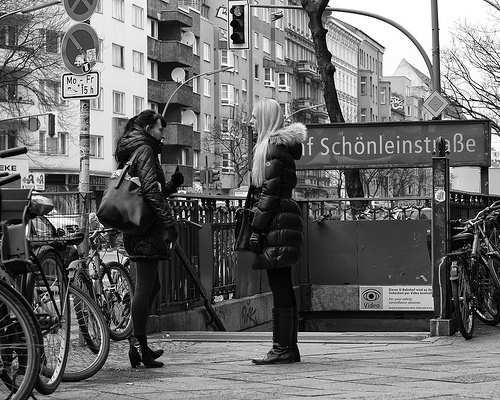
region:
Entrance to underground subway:
[212, 190, 449, 350]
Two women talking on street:
[102, 94, 327, 369]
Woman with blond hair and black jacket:
[230, 84, 314, 271]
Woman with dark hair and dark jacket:
[95, 102, 182, 260]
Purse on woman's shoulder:
[93, 161, 156, 240]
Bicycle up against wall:
[443, 193, 498, 341]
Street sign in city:
[52, 1, 106, 231]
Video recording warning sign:
[352, 283, 447, 316]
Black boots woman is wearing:
[246, 301, 310, 373]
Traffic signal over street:
[215, 0, 272, 56]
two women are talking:
[108, 91, 390, 395]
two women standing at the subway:
[85, 70, 383, 376]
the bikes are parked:
[6, 171, 138, 393]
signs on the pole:
[48, 6, 109, 274]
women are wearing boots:
[112, 255, 293, 399]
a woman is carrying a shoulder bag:
[94, 87, 210, 302]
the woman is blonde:
[234, 77, 316, 272]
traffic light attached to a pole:
[215, 5, 457, 88]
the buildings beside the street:
[86, 5, 439, 181]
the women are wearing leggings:
[107, 253, 360, 365]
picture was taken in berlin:
[0, 1, 498, 398]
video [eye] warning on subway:
[358, 284, 385, 309]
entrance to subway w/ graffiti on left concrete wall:
[215, 290, 436, 334]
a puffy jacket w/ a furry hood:
[230, 121, 309, 273]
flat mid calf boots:
[242, 301, 307, 370]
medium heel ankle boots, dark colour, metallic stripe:
[120, 328, 172, 374]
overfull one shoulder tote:
[94, 143, 158, 236]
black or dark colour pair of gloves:
[159, 163, 189, 260]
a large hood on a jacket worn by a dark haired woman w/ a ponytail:
[114, 107, 174, 161]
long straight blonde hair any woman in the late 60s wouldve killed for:
[249, 87, 287, 197]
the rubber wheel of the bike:
[32, 281, 114, 377]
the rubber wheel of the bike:
[0, 277, 36, 399]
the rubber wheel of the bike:
[70, 263, 102, 350]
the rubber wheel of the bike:
[94, 261, 138, 342]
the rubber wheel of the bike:
[447, 254, 475, 336]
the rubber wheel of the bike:
[471, 253, 498, 323]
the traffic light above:
[227, 1, 249, 47]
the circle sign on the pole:
[60, 26, 101, 71]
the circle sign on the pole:
[65, 0, 97, 17]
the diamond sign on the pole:
[421, 92, 449, 112]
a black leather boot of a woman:
[125, 336, 163, 370]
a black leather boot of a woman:
[145, 342, 162, 358]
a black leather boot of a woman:
[254, 307, 291, 366]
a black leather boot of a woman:
[287, 308, 302, 368]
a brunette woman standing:
[95, 109, 192, 367]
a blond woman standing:
[232, 96, 307, 362]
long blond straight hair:
[252, 96, 284, 187]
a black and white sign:
[60, 73, 98, 98]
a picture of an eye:
[362, 288, 385, 301]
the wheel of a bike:
[447, 258, 479, 338]